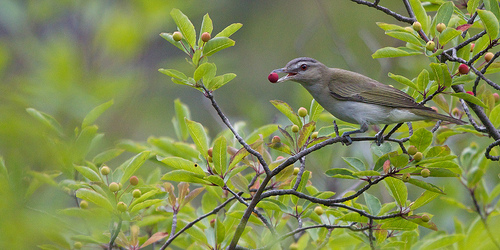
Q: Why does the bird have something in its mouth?
A: Eating.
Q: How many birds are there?
A: One.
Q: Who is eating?
A: The bird.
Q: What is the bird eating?
A: A berry.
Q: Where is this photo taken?
A: In a tree.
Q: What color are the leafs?
A: Green.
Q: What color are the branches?
A: Brown.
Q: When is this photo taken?
A: Daytime.